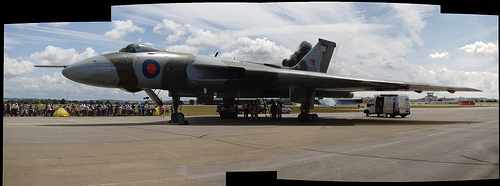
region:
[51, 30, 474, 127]
large jet is painted camoflage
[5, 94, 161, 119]
people standing on a runway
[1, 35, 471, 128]
people standing on a runway near a military plane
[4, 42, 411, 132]
people standing on a runway near a military jet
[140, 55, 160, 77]
red and white bullseye symbol painted on plane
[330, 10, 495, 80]
partly cloudy sky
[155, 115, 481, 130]
shadow of jet cast on runway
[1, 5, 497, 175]
panoramic view of people gathered to see jet on runway at airport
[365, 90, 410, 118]
white van with open doors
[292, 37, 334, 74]
tail of the airplane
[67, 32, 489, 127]
A very old jet fighter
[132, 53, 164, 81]
A circle that is red and blue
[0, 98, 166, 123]
People behind a fence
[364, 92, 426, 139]
A truck behind the jet fighter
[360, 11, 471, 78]
Lots of clouds in the sky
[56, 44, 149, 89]
The nose of a jet fighter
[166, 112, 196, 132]
Wheels on a jet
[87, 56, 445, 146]
A jet fighter parked on cement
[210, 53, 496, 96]
The wing on a plane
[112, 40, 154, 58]
The cockpit of a jet fighter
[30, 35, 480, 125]
jet plane on runway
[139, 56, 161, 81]
blue and orange circle on plane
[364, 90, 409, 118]
white van parked on runway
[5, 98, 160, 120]
crowd gathered on side of runway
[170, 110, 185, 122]
front wheels of runway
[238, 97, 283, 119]
group of people standing under airplane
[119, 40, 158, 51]
cockpit of airplane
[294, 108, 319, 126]
rear wheels of airplane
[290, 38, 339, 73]
tail fin of airplane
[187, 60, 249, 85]
air intake on jet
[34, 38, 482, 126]
Airplane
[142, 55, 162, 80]
Target logo on the left side of the airplane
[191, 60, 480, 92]
Left wing of the airplane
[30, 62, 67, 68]
Right wing of the airplane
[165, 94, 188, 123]
Front wheel of the airplane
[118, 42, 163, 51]
Front window of the airplane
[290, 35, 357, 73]
Tail of the airplane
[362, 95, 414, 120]
Small truck moving behind the airplane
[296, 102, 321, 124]
Set of wheels in the back of the plane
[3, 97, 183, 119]
Group of people standing next to the plane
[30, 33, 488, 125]
a big plane on a landing strip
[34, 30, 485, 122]
plane is color gray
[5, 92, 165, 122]
many people in front a plane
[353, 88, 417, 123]
a van behind a plane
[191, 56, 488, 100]
wing of plane is long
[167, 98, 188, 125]
front wheel of plane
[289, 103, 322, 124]
back wheels of plane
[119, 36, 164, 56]
window of cockpit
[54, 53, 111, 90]
nose of plane is long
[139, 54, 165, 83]
a blue and red circle